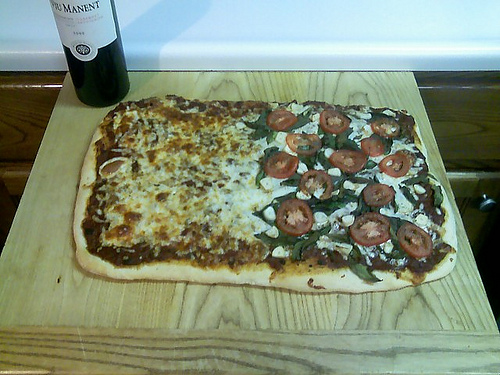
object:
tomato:
[299, 170, 332, 200]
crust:
[411, 120, 456, 282]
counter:
[0, 0, 500, 72]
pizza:
[72, 95, 452, 295]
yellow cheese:
[107, 109, 255, 250]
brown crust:
[80, 94, 451, 284]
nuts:
[262, 103, 431, 256]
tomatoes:
[350, 184, 431, 258]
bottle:
[50, 0, 130, 107]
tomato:
[364, 183, 395, 207]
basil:
[295, 107, 311, 128]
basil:
[318, 124, 359, 150]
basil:
[308, 195, 335, 212]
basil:
[255, 228, 318, 260]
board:
[0, 71, 500, 375]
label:
[50, 0, 118, 62]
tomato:
[397, 222, 432, 257]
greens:
[430, 182, 445, 209]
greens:
[389, 215, 404, 258]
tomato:
[265, 151, 298, 178]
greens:
[347, 246, 381, 283]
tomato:
[276, 198, 312, 235]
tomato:
[350, 212, 392, 245]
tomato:
[330, 149, 366, 173]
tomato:
[371, 117, 399, 137]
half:
[259, 100, 456, 293]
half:
[72, 93, 267, 287]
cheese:
[217, 167, 257, 230]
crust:
[72, 115, 92, 271]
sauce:
[83, 213, 99, 253]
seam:
[0, 325, 500, 375]